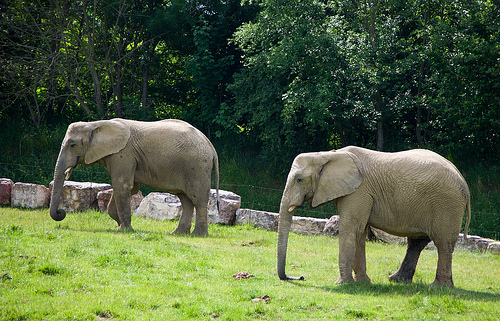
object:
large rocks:
[1, 175, 48, 210]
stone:
[94, 185, 139, 220]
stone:
[130, 185, 241, 225]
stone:
[178, 185, 235, 221]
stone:
[236, 204, 285, 228]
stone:
[288, 214, 325, 235]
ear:
[84, 120, 130, 164]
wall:
[2, 174, 490, 252]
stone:
[0, 176, 48, 209]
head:
[262, 152, 362, 226]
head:
[56, 119, 131, 174]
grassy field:
[0, 238, 172, 319]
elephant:
[277, 107, 471, 287]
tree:
[1, 0, 199, 115]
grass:
[136, 281, 314, 319]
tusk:
[277, 202, 303, 214]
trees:
[12, 12, 482, 115]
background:
[10, 4, 491, 231]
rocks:
[9, 180, 142, 210]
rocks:
[213, 188, 241, 224]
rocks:
[46, 177, 184, 220]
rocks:
[206, 187, 242, 224]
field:
[0, 202, 498, 319]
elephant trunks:
[49, 149, 69, 221]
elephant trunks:
[277, 189, 305, 280]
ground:
[220, 289, 497, 319]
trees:
[4, 0, 496, 174]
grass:
[22, 243, 265, 313]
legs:
[428, 209, 463, 291]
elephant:
[50, 117, 219, 237]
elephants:
[49, 117, 471, 290]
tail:
[212, 151, 220, 205]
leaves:
[228, 24, 308, 74]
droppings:
[229, 270, 261, 280]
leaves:
[330, 28, 460, 107]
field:
[2, 152, 495, 317]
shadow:
[373, 280, 494, 301]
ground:
[0, 209, 45, 318]